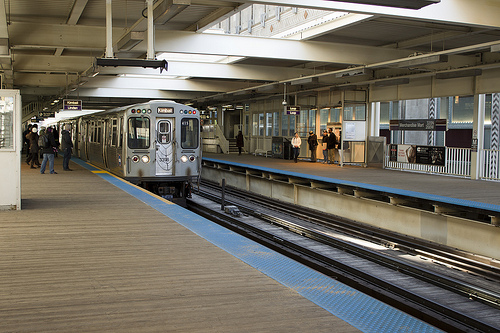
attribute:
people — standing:
[284, 127, 345, 163]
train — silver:
[74, 98, 217, 181]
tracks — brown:
[247, 225, 304, 254]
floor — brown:
[26, 222, 157, 308]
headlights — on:
[130, 149, 198, 166]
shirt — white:
[288, 137, 304, 148]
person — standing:
[58, 119, 74, 180]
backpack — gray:
[36, 133, 51, 150]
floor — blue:
[148, 204, 243, 258]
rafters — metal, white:
[170, 29, 310, 79]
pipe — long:
[217, 63, 459, 94]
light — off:
[279, 99, 298, 109]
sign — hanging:
[61, 98, 91, 115]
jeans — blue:
[42, 153, 58, 175]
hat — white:
[30, 127, 41, 134]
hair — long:
[27, 131, 39, 142]